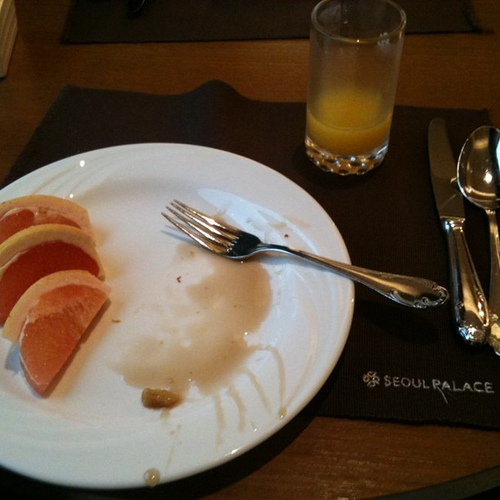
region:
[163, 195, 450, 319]
Silver fork on a white plate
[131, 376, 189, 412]
Crumbs of a finished meal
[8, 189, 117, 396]
Slices of grapefruit on a white plate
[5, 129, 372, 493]
A dirty white plate after a meal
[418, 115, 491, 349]
A silver knife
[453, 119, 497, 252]
SIlver spoon on a place mat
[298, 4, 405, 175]
A drinking glass on a place mat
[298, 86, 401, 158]
Orange juice in a glass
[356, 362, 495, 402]
White insignia on a place mat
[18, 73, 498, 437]
Black place mat on a wooden table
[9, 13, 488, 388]
half eaten breakfast on table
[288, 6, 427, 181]
glass of orange juice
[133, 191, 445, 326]
silver fork on plate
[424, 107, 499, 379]
silverware on brown placemat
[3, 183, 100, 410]
grapefruit wedges on plate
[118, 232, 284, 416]
syrup left on plate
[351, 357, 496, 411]
seoul palace embroidered on place mat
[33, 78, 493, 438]
brown place mat setting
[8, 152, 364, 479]
round white plate on table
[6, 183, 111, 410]
three pink grapefruit wedges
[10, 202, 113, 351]
grapefruit wedges on a white plate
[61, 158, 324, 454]
shiny white ceramic plate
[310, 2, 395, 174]
orange juice in a glass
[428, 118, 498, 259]
silverware on black placemat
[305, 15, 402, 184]
cup on black place mat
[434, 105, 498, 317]
silver knife and silver spoon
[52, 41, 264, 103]
brown wooden table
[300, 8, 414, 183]
glass with juice inside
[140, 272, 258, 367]
dirty white plate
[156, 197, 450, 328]
silver fork on a plate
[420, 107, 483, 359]
silve knife on a placemat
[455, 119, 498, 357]
silver spoon on a placemat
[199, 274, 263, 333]
syrup on a plate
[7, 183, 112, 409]
grapefruit slices on a plate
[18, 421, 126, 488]
white plate on a table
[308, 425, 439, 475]
wooden table where food is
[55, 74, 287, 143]
brown placemat on table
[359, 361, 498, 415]
stitched name on placemat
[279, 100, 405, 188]
Thick bottom on glass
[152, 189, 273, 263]
Four pronged fork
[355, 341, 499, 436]
Name of restaurant on placemat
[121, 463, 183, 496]
Syrup about to drip off plate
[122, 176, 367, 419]
Fork in syrup on plate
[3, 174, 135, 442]
Uneaten grapefruit left on plate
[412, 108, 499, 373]
Spoon and knife on placemat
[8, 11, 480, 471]
Mostly eaten breakfast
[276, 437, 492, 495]
Light brown wood table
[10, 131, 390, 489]
Breakfast on a white plate